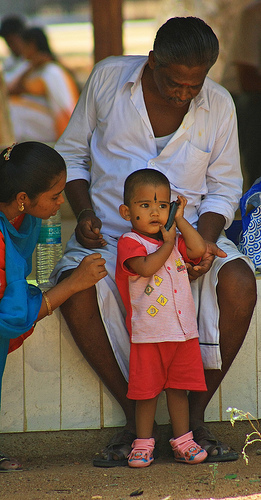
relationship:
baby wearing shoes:
[113, 175, 248, 366] [126, 438, 155, 469]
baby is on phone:
[115, 168, 207, 470] [161, 193, 182, 229]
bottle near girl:
[36, 208, 61, 289] [1, 140, 106, 386]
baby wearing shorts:
[115, 168, 207, 470] [126, 337, 208, 402]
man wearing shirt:
[40, 10, 253, 467] [53, 53, 243, 236]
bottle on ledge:
[36, 208, 63, 287] [23, 268, 259, 300]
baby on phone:
[115, 168, 207, 470] [161, 199, 179, 235]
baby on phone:
[115, 168, 207, 470] [157, 198, 177, 235]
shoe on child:
[168, 430, 208, 465] [113, 166, 215, 469]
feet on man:
[90, 421, 239, 468] [40, 10, 253, 467]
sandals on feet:
[91, 412, 240, 469] [90, 421, 239, 468]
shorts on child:
[114, 337, 208, 397] [111, 167, 220, 498]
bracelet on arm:
[43, 294, 49, 307] [49, 284, 69, 303]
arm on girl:
[49, 284, 69, 303] [1, 140, 108, 402]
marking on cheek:
[129, 210, 144, 223] [131, 204, 148, 230]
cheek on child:
[131, 204, 148, 230] [95, 155, 216, 476]